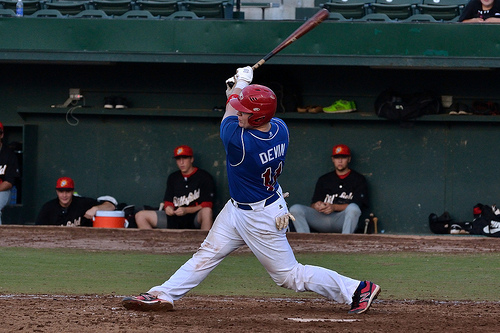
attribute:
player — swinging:
[119, 63, 381, 315]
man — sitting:
[291, 142, 370, 233]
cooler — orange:
[88, 210, 126, 228]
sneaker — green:
[323, 99, 354, 114]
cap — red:
[169, 146, 194, 161]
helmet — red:
[232, 83, 277, 127]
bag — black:
[375, 83, 442, 121]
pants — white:
[146, 185, 359, 304]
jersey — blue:
[219, 115, 290, 207]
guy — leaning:
[38, 178, 116, 226]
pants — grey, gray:
[290, 203, 362, 234]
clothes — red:
[470, 204, 498, 233]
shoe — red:
[351, 278, 381, 316]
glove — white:
[234, 67, 255, 84]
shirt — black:
[165, 167, 212, 209]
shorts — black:
[156, 210, 201, 226]